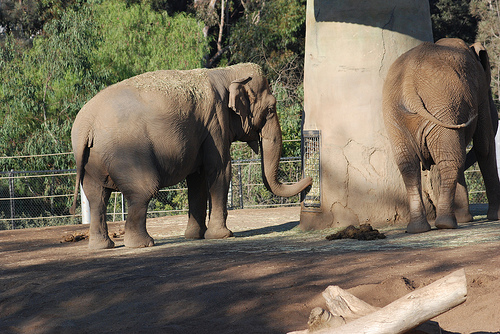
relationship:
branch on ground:
[286, 268, 468, 333] [2, 203, 499, 333]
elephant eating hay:
[68, 61, 313, 250] [304, 151, 319, 207]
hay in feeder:
[304, 151, 319, 207] [301, 129, 323, 208]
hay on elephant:
[126, 63, 269, 105] [68, 61, 313, 250]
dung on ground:
[325, 222, 385, 242] [2, 203, 499, 333]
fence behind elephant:
[2, 137, 489, 232] [68, 61, 313, 250]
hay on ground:
[100, 205, 498, 257] [2, 203, 499, 333]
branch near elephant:
[286, 268, 468, 333] [68, 61, 313, 250]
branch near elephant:
[286, 268, 468, 333] [383, 36, 499, 235]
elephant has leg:
[68, 61, 313, 250] [107, 126, 159, 249]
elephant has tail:
[68, 61, 313, 250] [70, 124, 93, 214]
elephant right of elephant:
[383, 36, 499, 235] [68, 61, 313, 250]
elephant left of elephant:
[68, 61, 313, 250] [383, 36, 499, 235]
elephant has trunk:
[68, 61, 313, 250] [257, 116, 314, 197]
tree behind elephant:
[2, 1, 206, 217] [68, 61, 313, 250]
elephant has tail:
[383, 36, 499, 235] [401, 93, 481, 130]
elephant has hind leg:
[68, 61, 313, 250] [80, 167, 116, 250]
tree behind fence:
[2, 1, 206, 217] [2, 137, 489, 232]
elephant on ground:
[68, 61, 313, 250] [2, 203, 499, 333]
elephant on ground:
[383, 36, 499, 235] [2, 203, 499, 333]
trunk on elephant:
[257, 116, 314, 197] [68, 61, 313, 250]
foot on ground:
[122, 230, 155, 249] [2, 203, 499, 333]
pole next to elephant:
[77, 177, 91, 226] [68, 61, 313, 250]